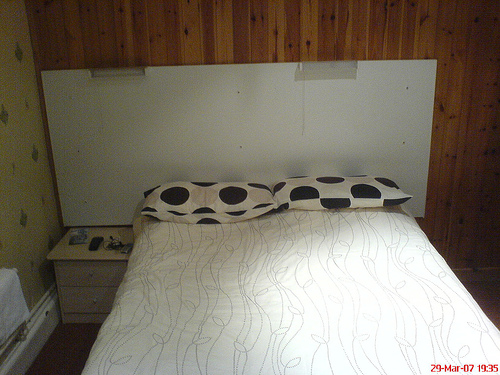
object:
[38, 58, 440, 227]
board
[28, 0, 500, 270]
wall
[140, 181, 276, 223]
pillows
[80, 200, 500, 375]
bed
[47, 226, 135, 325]
stand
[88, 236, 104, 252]
items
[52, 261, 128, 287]
drawers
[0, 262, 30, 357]
heater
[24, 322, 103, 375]
floor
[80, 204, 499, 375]
sheet